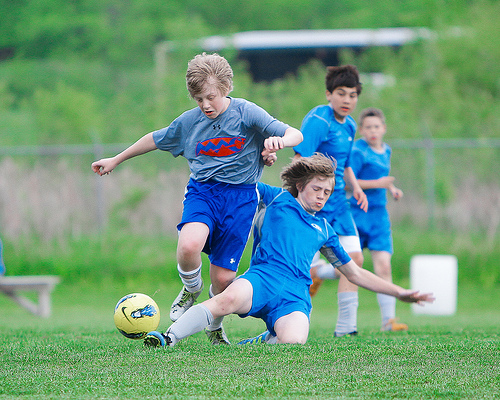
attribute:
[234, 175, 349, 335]
uniform — blue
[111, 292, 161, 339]
soccer ball — yellow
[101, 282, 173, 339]
ball — soccer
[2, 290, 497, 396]
grass — green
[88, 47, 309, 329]
boy — wearing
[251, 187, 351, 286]
shirt — gray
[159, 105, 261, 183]
uniform — blue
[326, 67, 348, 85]
dark hair — short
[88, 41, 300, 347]
boy — running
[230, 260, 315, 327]
shorts — blue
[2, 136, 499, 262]
fence — metal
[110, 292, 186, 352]
soccer ball — yellow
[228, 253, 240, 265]
logo — white, small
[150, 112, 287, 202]
shirt — short sleeved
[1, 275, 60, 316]
bench — wooden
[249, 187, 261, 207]
stripe — white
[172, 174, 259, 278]
shorts — blue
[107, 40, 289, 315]
boy — short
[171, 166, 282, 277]
pants — blue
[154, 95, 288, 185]
shirt — blue